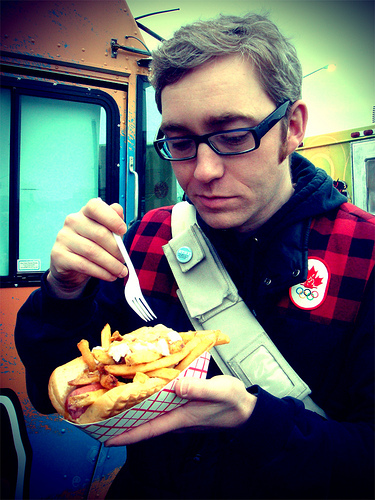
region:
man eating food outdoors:
[13, 10, 372, 498]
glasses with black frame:
[153, 99, 289, 160]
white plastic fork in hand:
[50, 196, 156, 322]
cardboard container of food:
[50, 320, 226, 442]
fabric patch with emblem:
[287, 255, 330, 309]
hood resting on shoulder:
[257, 150, 348, 247]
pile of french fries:
[70, 320, 229, 386]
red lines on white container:
[68, 353, 211, 443]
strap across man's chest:
[16, 11, 373, 420]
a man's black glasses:
[147, 96, 294, 163]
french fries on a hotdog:
[74, 322, 228, 379]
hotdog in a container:
[35, 323, 209, 421]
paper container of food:
[54, 348, 210, 446]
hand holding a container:
[92, 371, 250, 450]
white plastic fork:
[109, 226, 159, 327]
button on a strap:
[173, 245, 194, 265]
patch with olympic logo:
[287, 253, 329, 312]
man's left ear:
[289, 97, 308, 158]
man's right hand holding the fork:
[46, 196, 130, 291]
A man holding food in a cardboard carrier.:
[25, 9, 373, 495]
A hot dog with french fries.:
[41, 314, 231, 438]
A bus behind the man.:
[4, 3, 167, 483]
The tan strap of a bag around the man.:
[150, 15, 372, 458]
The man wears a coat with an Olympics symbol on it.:
[14, 13, 374, 499]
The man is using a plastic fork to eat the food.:
[17, 12, 359, 480]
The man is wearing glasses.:
[144, 9, 322, 229]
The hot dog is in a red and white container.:
[51, 315, 224, 444]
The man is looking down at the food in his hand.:
[14, 10, 372, 496]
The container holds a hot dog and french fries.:
[30, 316, 234, 434]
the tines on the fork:
[123, 272, 155, 321]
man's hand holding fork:
[52, 201, 158, 318]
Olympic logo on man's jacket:
[285, 250, 326, 309]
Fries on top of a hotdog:
[36, 315, 232, 440]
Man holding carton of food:
[25, 298, 288, 460]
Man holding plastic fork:
[65, 186, 180, 327]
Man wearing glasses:
[145, 88, 311, 169]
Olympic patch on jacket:
[281, 255, 330, 310]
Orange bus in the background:
[2, 0, 160, 498]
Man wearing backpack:
[160, 196, 332, 427]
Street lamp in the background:
[301, 63, 334, 80]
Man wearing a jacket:
[12, 146, 373, 497]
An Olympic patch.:
[284, 246, 336, 315]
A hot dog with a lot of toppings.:
[41, 304, 231, 452]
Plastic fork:
[81, 194, 171, 333]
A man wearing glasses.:
[145, 12, 315, 235]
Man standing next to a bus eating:
[3, 1, 364, 466]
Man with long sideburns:
[123, 13, 318, 228]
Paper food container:
[55, 342, 218, 450]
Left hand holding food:
[43, 314, 261, 447]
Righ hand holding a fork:
[24, 181, 162, 326]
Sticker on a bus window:
[17, 255, 41, 274]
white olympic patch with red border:
[287, 255, 329, 309]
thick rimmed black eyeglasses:
[153, 99, 291, 161]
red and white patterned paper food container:
[60, 348, 209, 442]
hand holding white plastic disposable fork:
[51, 196, 157, 321]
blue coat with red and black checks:
[14, 151, 374, 499]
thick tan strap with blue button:
[162, 201, 326, 417]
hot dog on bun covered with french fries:
[47, 323, 229, 423]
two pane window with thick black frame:
[0, 74, 119, 287]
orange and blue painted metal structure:
[0, 0, 154, 498]